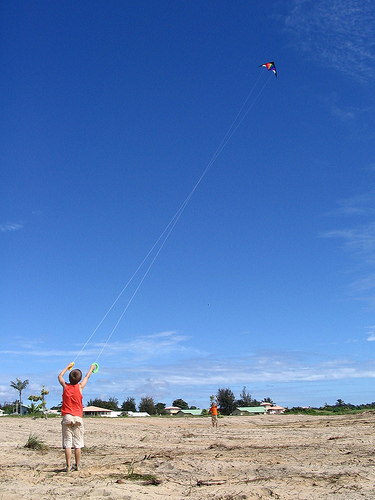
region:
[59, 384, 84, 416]
the shirt is orange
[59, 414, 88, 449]
the pants are tan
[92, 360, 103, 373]
the handel is green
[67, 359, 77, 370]
the handle is yellow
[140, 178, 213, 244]
string is attached to the kite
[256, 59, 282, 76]
the kite is black red and purple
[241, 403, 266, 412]
the roof is green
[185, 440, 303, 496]
the sand is brown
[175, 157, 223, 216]
the strings are crisscrossed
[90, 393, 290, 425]
houses are in the background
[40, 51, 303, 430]
this is along a coast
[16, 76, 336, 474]
this is at a beach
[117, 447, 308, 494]
the ground here is sandy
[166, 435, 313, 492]
the sand is light brown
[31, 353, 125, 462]
this is a child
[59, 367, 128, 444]
the kid is flying a kite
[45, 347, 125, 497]
the kit is holding a kite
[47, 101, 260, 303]
these are kite wires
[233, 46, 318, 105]
this is a kite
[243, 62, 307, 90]
the kite is rainbow colored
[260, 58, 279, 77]
triangular kite in air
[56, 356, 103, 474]
boy flying kite on beach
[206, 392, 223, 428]
man waving to little boy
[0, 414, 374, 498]
rutted sand on beach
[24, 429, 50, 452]
patch of tall grass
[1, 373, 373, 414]
tree line in distance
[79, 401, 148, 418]
house and buildings behind boy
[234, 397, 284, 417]
buildings to right of man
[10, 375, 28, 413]
palm tree in distance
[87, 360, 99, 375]
green kite handle in man's hand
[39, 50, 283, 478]
A young boy flying a kite